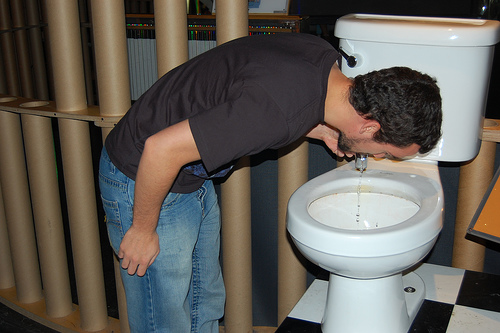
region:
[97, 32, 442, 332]
man in black t-shirt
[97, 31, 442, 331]
man in jeans looking in a toilet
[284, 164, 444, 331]
man looking in the toilet bowl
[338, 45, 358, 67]
silver handle to the toilet tank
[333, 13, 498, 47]
white toilet top to the tank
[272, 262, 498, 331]
black and white tiles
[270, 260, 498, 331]
tiles under the the toilet set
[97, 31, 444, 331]
a man inspecting the toilet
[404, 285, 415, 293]
a metal bolt on the bottom side of the toilet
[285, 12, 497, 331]
man looking at a white toilet on display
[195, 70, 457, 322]
the toilet bowl is white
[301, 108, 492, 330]
the toilet bowl is white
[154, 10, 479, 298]
a man vomiting in a toilet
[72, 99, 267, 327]
a man wearing blue jeans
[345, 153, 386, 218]
a liquid falling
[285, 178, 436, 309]
a white porcelain toilet bowl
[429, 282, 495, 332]
black and white tile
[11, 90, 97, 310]
set of cardboard tubing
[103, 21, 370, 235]
a man in a brown shirt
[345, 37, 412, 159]
a brunette man with a beard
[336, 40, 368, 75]
handle to flush the toilet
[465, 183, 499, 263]
an orange sign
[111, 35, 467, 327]
Man leaning over a toilet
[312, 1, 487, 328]
The toilet is white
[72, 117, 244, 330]
Jeans on the man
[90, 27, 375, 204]
Black t-shirt on the man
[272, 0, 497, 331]
The toilet is on a platform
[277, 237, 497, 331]
The platform is white and black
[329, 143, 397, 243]
The man is spitting into the toilet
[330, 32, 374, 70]
Toilet lever is silver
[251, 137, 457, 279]
No seat on the toilet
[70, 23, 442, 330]
Man wearing jeans and a t-shirt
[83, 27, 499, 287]
a man with head over toilet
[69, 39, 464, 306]
a man wearing gray shirt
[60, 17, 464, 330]
a man wearing blue jeans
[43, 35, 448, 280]
a an wearing jeans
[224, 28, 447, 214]
a man with dark hair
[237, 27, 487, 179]
a man with short hair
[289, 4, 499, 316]
a white bathroom toilet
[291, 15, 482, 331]
a whtie toilet on display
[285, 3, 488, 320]
a toilet on display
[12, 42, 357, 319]
brown posts